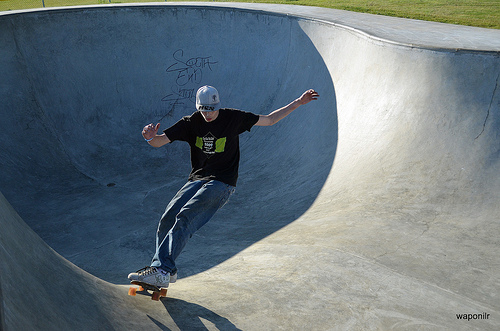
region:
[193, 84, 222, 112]
a gray baseball cap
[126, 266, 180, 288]
a white pair of shoes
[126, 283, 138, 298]
an orange wheel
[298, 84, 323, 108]
the hand of a boy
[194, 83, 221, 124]
the head of a boy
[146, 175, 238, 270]
a pair of blue jeans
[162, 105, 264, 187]
a black tee shirt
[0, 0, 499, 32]
a green grassy field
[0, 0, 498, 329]
a gray skate park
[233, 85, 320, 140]
the arm of a boy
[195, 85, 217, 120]
The hat the skateboarder is wearing.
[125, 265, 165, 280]
The white sneaker the skateboarder is wearing.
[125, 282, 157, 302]
The front wheels on the skateboard.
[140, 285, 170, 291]
The back wheels on the skateboard.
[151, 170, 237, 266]
The blue jeans the skateboarder is wearing.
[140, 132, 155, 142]
The bracelet/band on the skateboarder's wrist.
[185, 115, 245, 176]
The black t-shirt the skateboarder is wearing.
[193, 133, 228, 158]
The design on the skateboarder's shirt.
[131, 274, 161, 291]
The tip of the skateboard.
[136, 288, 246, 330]
The shadow on the ground of the skateboarder.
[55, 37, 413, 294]
There is a male skateboading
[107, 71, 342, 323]
The skateboarder is wearing a black shirt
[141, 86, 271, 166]
The skate boarder is wearing a cap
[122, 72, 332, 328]
The skateboarder is wearing jeans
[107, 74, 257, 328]
The skateboarder is wearing sneakers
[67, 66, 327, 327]
There is only one skateboarder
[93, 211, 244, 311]
The skateboard has orange wheels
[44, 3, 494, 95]
There is grass in the background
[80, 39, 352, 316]
There is graffiti in the back of the skateboarder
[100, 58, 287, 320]
There is a green color on the shirt of the skateboarder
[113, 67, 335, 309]
A young man is skateboarding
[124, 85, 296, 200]
The young man is wearing a black shirt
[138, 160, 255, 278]
The young man is wearing blue jeans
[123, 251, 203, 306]
The young man is wearing white shoes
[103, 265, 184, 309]
The skateboard's wheels are orange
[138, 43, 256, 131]
The skateboard ram has writing on the side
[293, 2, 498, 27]
Green grass is in the background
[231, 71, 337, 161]
Young man has his hand out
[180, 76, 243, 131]
Man is wearing a cap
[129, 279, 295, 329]
The man skateboarding is casting a shadow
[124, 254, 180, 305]
A skateboard with orange wheels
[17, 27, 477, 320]
A skateboard park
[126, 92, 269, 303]
A guy in a black shirt skateboarding.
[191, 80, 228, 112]
A grey knit cap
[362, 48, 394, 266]
Steep wall of a skateboard park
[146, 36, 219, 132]
Some graffiti on the wall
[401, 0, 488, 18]
Grass above the skateboard park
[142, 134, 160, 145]
a bracelet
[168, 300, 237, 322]
The shadow of a skateboarder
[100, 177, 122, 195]
A drain for water